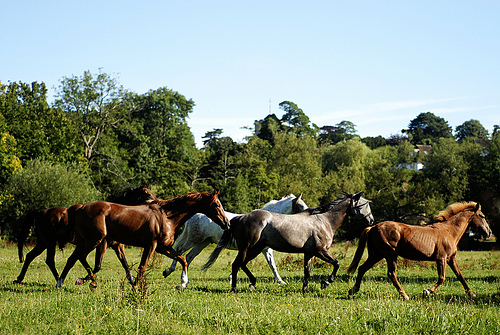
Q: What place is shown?
A: It is a field.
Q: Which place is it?
A: It is a field.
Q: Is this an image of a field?
A: Yes, it is showing a field.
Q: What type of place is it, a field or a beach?
A: It is a field.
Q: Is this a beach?
A: No, it is a field.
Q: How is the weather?
A: It is cloudy.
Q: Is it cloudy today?
A: Yes, it is cloudy.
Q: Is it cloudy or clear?
A: It is cloudy.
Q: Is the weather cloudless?
A: No, it is cloudy.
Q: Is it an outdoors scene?
A: Yes, it is outdoors.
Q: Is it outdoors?
A: Yes, it is outdoors.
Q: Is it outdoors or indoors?
A: It is outdoors.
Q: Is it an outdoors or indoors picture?
A: It is outdoors.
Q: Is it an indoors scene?
A: No, it is outdoors.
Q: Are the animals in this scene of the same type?
A: Yes, all the animals are horses.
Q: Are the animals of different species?
A: No, all the animals are horses.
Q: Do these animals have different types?
A: No, all the animals are horses.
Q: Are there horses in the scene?
A: Yes, there is a horse.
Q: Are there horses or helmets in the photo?
A: Yes, there is a horse.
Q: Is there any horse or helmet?
A: Yes, there is a horse.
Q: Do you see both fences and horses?
A: No, there is a horse but no fences.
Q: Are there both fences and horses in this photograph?
A: No, there is a horse but no fences.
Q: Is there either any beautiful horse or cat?
A: Yes, there is a beautiful horse.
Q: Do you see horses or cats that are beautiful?
A: Yes, the horse is beautiful.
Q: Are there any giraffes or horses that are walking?
A: Yes, the horse is walking.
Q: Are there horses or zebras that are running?
A: Yes, the horse is running.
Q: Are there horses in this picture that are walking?
A: Yes, there is a horse that is walking.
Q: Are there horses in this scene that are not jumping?
A: Yes, there is a horse that is walking.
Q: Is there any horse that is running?
A: Yes, there is a horse that is running.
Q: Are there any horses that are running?
A: Yes, there is a horse that is running.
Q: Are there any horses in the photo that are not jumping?
A: Yes, there is a horse that is running.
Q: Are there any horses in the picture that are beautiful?
A: Yes, there is a horse that is beautiful.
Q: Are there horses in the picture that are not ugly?
A: Yes, there is an beautiful horse.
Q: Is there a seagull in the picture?
A: No, there are no seagulls.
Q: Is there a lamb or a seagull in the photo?
A: No, there are no seagulls or lambs.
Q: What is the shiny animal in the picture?
A: The animal is a horse.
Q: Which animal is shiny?
A: The animal is a horse.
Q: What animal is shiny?
A: The animal is a horse.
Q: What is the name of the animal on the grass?
A: The animal is a horse.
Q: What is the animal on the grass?
A: The animal is a horse.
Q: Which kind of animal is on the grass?
A: The animal is a horse.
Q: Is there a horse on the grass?
A: Yes, there is a horse on the grass.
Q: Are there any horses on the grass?
A: Yes, there is a horse on the grass.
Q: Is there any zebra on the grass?
A: No, there is a horse on the grass.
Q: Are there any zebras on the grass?
A: No, there is a horse on the grass.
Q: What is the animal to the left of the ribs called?
A: The animal is a horse.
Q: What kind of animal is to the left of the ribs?
A: The animal is a horse.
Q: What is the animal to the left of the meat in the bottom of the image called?
A: The animal is a horse.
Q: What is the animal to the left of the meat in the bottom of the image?
A: The animal is a horse.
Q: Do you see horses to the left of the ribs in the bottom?
A: Yes, there is a horse to the left of the ribs.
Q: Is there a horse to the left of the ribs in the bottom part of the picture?
A: Yes, there is a horse to the left of the ribs.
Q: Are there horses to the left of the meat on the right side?
A: Yes, there is a horse to the left of the ribs.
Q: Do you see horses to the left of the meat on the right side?
A: Yes, there is a horse to the left of the ribs.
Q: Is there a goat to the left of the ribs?
A: No, there is a horse to the left of the ribs.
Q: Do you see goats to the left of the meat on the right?
A: No, there is a horse to the left of the ribs.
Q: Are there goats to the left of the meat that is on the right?
A: No, there is a horse to the left of the ribs.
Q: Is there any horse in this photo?
A: Yes, there is a horse.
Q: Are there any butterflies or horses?
A: Yes, there is a horse.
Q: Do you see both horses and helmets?
A: No, there is a horse but no helmets.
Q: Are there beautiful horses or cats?
A: Yes, there is a beautiful horse.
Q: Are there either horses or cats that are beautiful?
A: Yes, the horse is beautiful.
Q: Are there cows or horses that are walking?
A: Yes, the horse is walking.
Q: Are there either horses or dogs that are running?
A: Yes, the horse is running.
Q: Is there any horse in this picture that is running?
A: Yes, there is a horse that is running.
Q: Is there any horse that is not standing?
A: Yes, there is a horse that is running.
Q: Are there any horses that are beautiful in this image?
A: Yes, there is a beautiful horse.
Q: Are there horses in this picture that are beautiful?
A: Yes, there is a horse that is beautiful.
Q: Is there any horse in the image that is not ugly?
A: Yes, there is an beautiful horse.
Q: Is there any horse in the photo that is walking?
A: Yes, there is a horse that is walking.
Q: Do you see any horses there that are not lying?
A: Yes, there is a horse that is walking .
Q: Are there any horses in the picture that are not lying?
A: Yes, there is a horse that is walking.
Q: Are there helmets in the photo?
A: No, there are no helmets.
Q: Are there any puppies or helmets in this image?
A: No, there are no helmets or puppies.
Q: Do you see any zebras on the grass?
A: No, there is a horse on the grass.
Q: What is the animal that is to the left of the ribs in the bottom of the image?
A: The animal is a horse.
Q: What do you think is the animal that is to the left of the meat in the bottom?
A: The animal is a horse.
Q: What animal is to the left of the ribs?
A: The animal is a horse.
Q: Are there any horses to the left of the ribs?
A: Yes, there is a horse to the left of the ribs.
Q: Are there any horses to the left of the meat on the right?
A: Yes, there is a horse to the left of the ribs.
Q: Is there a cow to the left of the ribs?
A: No, there is a horse to the left of the ribs.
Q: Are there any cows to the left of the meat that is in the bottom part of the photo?
A: No, there is a horse to the left of the ribs.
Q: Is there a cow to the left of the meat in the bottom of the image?
A: No, there is a horse to the left of the ribs.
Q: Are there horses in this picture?
A: Yes, there is a horse.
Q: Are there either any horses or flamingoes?
A: Yes, there is a horse.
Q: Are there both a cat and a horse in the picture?
A: No, there is a horse but no cats.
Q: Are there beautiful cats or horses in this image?
A: Yes, there is a beautiful horse.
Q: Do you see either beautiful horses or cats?
A: Yes, there is a beautiful horse.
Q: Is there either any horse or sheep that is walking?
A: Yes, the horse is walking.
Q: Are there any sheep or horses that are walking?
A: Yes, the horse is walking.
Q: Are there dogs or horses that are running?
A: Yes, the horse is running.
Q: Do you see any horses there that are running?
A: Yes, there is a horse that is running.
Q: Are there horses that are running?
A: Yes, there is a horse that is running.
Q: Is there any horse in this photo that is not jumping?
A: Yes, there is a horse that is walking.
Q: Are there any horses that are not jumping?
A: Yes, there is a horse that is walking.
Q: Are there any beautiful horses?
A: Yes, there is a beautiful horse.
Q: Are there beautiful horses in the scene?
A: Yes, there is a beautiful horse.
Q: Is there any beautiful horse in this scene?
A: Yes, there is a beautiful horse.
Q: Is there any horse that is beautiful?
A: Yes, there is a horse that is beautiful.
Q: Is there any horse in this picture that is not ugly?
A: Yes, there is an beautiful horse.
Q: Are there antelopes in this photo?
A: No, there are no antelopes.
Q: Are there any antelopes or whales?
A: No, there are no antelopes or whales.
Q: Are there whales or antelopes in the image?
A: No, there are no antelopes or whales.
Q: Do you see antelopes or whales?
A: No, there are no antelopes or whales.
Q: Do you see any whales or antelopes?
A: No, there are no antelopes or whales.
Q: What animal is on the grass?
A: The animal is a horse.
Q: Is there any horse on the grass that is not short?
A: Yes, there is a horse on the grass.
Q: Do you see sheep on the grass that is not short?
A: No, there is a horse on the grass.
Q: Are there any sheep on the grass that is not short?
A: No, there is a horse on the grass.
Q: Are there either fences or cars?
A: No, there are no fences or cars.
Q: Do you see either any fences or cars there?
A: No, there are no fences or cars.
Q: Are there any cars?
A: No, there are no cars.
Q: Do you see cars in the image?
A: No, there are no cars.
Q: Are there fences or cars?
A: No, there are no cars or fences.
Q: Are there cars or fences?
A: No, there are no cars or fences.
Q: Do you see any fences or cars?
A: No, there are no cars or fences.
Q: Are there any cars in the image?
A: No, there are no cars.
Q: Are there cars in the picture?
A: No, there are no cars.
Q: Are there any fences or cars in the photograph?
A: No, there are no cars or fences.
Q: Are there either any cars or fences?
A: No, there are no cars or fences.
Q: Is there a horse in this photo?
A: Yes, there is a horse.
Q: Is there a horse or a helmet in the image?
A: Yes, there is a horse.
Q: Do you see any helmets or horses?
A: Yes, there is a horse.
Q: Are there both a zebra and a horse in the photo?
A: No, there is a horse but no zebras.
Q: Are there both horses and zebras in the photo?
A: No, there is a horse but no zebras.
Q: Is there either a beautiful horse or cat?
A: Yes, there is a beautiful horse.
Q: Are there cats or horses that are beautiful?
A: Yes, the horse is beautiful.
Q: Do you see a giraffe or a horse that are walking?
A: Yes, the horse is walking.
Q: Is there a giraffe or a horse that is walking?
A: Yes, the horse is walking.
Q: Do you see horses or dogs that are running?
A: Yes, the horse is running.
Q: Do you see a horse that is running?
A: Yes, there is a horse that is running.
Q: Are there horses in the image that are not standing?
A: Yes, there is a horse that is running.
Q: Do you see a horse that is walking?
A: Yes, there is a horse that is walking.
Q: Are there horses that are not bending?
A: Yes, there is a horse that is walking.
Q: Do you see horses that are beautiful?
A: Yes, there is a beautiful horse.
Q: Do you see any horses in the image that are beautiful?
A: Yes, there is a horse that is beautiful.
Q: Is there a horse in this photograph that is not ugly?
A: Yes, there is an beautiful horse.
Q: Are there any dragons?
A: No, there are no dragons.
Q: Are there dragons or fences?
A: No, there are no dragons or fences.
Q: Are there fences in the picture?
A: No, there are no fences.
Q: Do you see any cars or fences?
A: No, there are no fences or cars.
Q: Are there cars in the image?
A: No, there are no cars.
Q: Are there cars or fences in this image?
A: No, there are no cars or fences.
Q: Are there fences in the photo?
A: No, there are no fences.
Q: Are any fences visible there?
A: No, there are no fences.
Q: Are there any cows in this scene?
A: No, there are no cows.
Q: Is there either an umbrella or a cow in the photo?
A: No, there are no cows or umbrellas.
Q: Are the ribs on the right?
A: Yes, the ribs are on the right of the image.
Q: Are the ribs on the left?
A: No, the ribs are on the right of the image.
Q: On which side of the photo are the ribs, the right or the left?
A: The ribs are on the right of the image.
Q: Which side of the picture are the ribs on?
A: The ribs are on the right of the image.